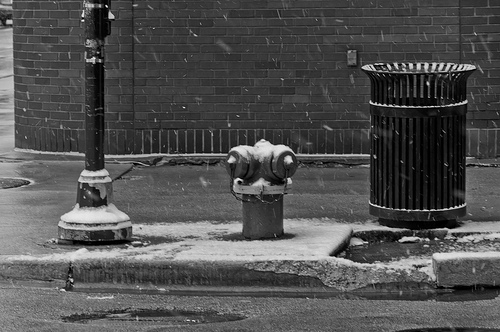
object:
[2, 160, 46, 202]
manhole cover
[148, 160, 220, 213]
sidewalk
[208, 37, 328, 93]
brick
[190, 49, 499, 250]
can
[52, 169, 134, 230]
snow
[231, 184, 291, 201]
chains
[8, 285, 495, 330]
street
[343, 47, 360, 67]
box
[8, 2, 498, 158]
wall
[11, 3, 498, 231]
building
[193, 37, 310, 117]
wall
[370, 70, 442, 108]
ground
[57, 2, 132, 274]
street light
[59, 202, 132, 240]
snow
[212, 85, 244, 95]
brick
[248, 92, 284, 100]
brick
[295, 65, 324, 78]
brick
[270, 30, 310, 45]
brick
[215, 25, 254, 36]
brick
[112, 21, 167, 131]
wall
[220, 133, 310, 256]
fire hydrant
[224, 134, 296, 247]
hydrant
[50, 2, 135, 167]
pole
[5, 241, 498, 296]
curb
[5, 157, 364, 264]
sidewalk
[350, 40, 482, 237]
bin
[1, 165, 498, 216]
sidewalk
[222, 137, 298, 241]
fire hydrant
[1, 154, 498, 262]
sidewalk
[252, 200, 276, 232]
hydrant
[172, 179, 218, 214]
sidewalk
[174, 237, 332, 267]
snow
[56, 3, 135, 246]
pole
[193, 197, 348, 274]
snow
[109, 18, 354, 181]
snow bits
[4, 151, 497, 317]
sidewalk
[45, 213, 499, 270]
snow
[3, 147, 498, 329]
ground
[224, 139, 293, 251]
snow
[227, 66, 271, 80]
brick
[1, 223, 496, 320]
curb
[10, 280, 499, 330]
road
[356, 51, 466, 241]
trash can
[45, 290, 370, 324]
sidewalk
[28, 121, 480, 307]
sidewalk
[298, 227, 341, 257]
white letter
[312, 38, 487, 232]
trash can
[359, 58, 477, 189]
bin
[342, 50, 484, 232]
trash can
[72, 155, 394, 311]
snow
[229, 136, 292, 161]
snow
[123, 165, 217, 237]
sidewalk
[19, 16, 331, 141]
building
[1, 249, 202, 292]
curb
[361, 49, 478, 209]
trash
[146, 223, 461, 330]
sidewalk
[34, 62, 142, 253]
pole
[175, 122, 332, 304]
fire hyrdrant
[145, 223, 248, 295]
ground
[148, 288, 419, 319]
ground